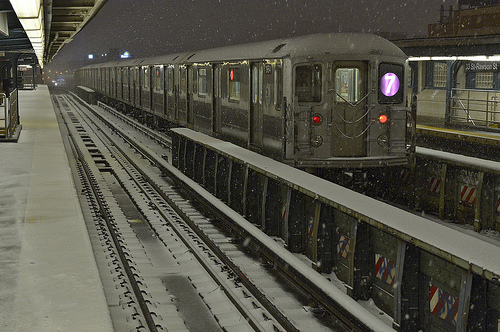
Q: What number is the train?
A: 7.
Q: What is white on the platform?
A: Snow.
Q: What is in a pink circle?
A: The 7.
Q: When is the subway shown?
A: Winter night.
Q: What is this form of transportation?
A: Train.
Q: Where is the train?
A: At a station.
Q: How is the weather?
A: Snowy.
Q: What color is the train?
A: Grey.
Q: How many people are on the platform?
A: Zero.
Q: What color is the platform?
A: White.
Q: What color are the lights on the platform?
A: White.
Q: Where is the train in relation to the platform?
A: To the right.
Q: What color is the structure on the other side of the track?
A: White and blue.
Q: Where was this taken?
A: Train station.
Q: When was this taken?
A: Winter.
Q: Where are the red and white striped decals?
A: On the barriers.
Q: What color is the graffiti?
A: Blue.